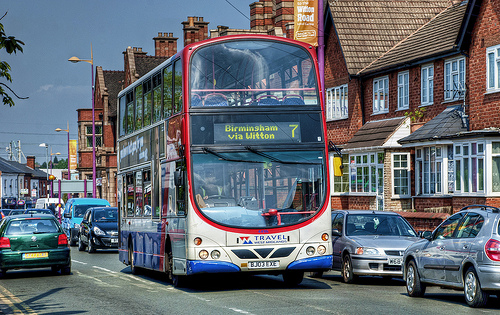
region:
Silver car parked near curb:
[400, 209, 496, 305]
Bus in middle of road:
[109, 31, 333, 289]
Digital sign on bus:
[208, 113, 306, 148]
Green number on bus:
[280, 113, 306, 143]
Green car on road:
[1, 206, 79, 281]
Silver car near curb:
[333, 202, 419, 284]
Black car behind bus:
[80, 204, 127, 261]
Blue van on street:
[59, 190, 110, 241]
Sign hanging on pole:
[62, 137, 85, 173]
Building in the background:
[0, 149, 60, 208]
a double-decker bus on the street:
[98, 29, 335, 283]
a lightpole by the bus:
[310, 0, 335, 114]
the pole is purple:
[313, 0, 330, 117]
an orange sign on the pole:
[287, 0, 319, 49]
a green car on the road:
[1, 211, 73, 271]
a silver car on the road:
[325, 204, 415, 281]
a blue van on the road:
[57, 189, 112, 241]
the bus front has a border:
[181, 30, 331, 237]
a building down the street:
[0, 149, 22, 206]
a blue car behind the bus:
[78, 203, 124, 252]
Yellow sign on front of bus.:
[211, 121, 304, 143]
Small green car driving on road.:
[5, 212, 72, 277]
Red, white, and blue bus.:
[115, 34, 335, 277]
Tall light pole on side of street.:
[67, 53, 107, 214]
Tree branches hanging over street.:
[0, 3, 30, 128]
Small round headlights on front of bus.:
[196, 246, 330, 260]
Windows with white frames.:
[367, 57, 468, 115]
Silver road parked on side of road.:
[401, 197, 498, 311]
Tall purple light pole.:
[89, 62, 99, 212]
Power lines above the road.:
[1, 119, 78, 167]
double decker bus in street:
[115, 30, 342, 298]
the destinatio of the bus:
[215, 121, 307, 141]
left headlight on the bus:
[320, 233, 330, 240]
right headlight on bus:
[187, 233, 201, 245]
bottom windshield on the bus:
[194, 148, 332, 227]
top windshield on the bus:
[187, 40, 315, 106]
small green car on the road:
[0, 215, 78, 272]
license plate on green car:
[23, 249, 50, 259]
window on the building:
[393, 69, 409, 107]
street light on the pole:
[56, 53, 92, 71]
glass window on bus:
[115, 93, 127, 134]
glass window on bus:
[124, 93, 136, 130]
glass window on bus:
[132, 83, 146, 131]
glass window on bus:
[142, 78, 153, 125]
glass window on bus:
[160, 68, 171, 115]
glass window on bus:
[170, 59, 183, 116]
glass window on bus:
[194, 41, 318, 107]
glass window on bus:
[194, 152, 326, 229]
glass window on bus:
[139, 169, 151, 216]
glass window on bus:
[124, 173, 134, 218]